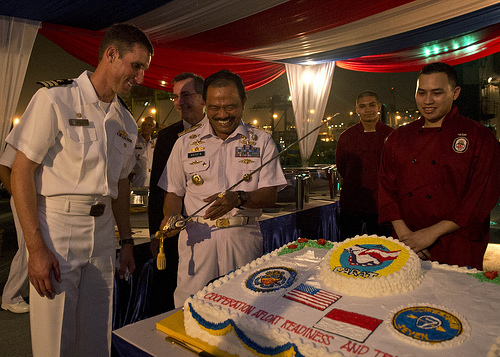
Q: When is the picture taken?
A: Night time.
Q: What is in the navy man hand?
A: Sword.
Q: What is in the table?
A: Cake.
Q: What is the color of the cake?
A: Mainly white.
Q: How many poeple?
A: 6.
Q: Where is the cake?
A: Table.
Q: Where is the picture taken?
A: At the marine celebration.